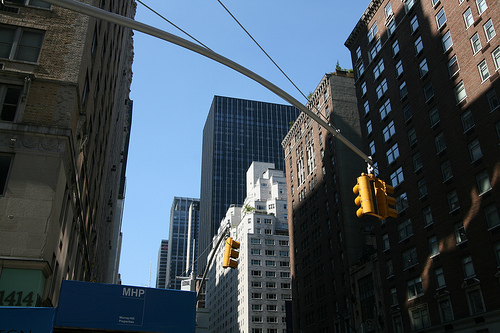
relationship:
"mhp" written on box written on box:
[116, 277, 151, 305] [78, 266, 190, 313]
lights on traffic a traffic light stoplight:
[183, 220, 272, 294] [351, 171, 403, 223]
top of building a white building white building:
[230, 158, 314, 235] [236, 151, 300, 275]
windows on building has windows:
[342, 5, 498, 325] [342, 0, 499, 331]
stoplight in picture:
[351, 171, 379, 217] [4, 3, 494, 331]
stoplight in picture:
[351, 171, 403, 223] [4, 3, 494, 331]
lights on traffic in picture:
[220, 237, 243, 270] [4, 3, 494, 331]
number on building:
[4, 289, 33, 307] [2, 0, 132, 303]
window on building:
[8, 18, 51, 72] [4, 32, 100, 272]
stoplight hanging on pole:
[351, 171, 403, 223] [269, 83, 383, 171]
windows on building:
[251, 225, 283, 304] [223, 185, 328, 315]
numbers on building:
[2, 280, 36, 319] [0, 65, 118, 319]